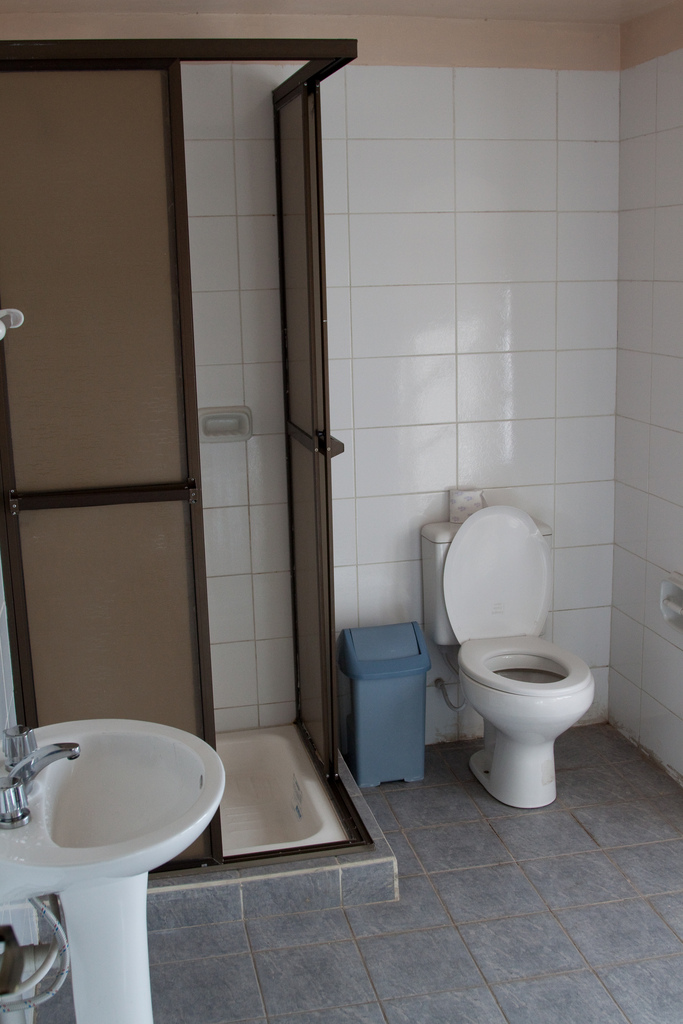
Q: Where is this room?
A: In a bathroom.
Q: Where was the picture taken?
A: In a bathroom.